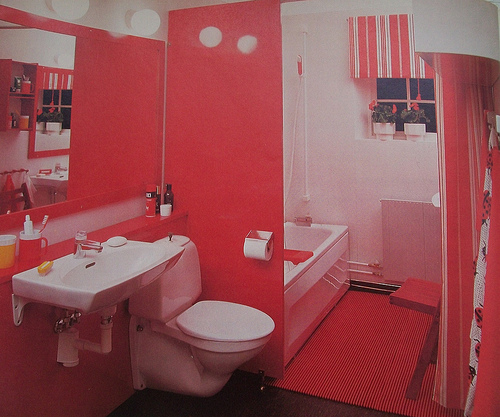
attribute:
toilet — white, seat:
[139, 277, 306, 376]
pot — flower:
[343, 80, 439, 163]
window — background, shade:
[362, 60, 455, 130]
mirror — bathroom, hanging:
[11, 31, 117, 217]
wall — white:
[274, 62, 370, 201]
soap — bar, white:
[104, 224, 125, 246]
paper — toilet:
[221, 206, 286, 271]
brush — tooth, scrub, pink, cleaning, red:
[35, 179, 64, 241]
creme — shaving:
[134, 163, 168, 224]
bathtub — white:
[242, 179, 363, 344]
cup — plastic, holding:
[15, 236, 44, 266]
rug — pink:
[374, 268, 448, 330]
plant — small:
[355, 86, 439, 145]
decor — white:
[226, 28, 257, 67]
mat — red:
[303, 289, 401, 396]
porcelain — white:
[30, 260, 125, 313]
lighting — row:
[67, 8, 266, 65]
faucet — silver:
[65, 205, 114, 265]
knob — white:
[425, 188, 443, 211]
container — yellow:
[0, 228, 24, 261]